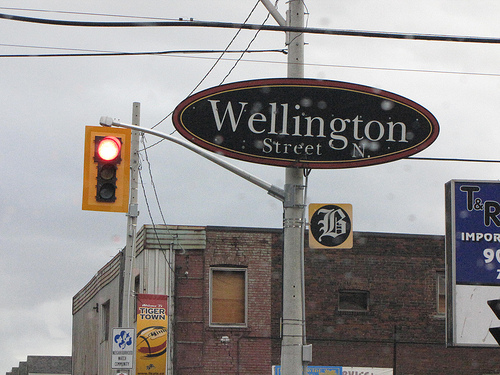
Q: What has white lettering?
A: Large oval black sign.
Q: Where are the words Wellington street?
A: On the sign.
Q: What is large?
A: Red brick building.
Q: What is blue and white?
A: Business sign.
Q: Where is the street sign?
A: On the Wellington sign.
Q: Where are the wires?
A: Above sign.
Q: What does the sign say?
A: Wellington street n.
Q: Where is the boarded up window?
A: On left.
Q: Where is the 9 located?
A: On sign to right.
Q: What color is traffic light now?
A: Red.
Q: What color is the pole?
A: Grey.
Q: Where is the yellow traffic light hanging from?
A: Pole.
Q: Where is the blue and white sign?
A: On right.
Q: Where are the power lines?
A: On pole.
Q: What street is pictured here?
A: Wellington Street.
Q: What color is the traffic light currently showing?
A: Red.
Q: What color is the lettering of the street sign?
A: White.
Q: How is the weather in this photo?
A: Cloudy.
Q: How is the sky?
A: Overcast.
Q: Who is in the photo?
A: No one.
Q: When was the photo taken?
A: Evening.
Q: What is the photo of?
A: A sign of wellington street.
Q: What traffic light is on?
A: The red light.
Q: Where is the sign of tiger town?
A: On the building.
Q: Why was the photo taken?
A: To show a street.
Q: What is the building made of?
A: Bricks.